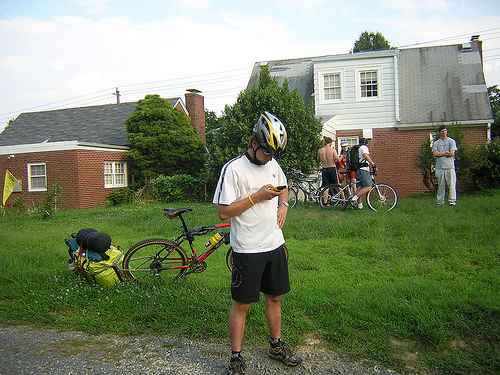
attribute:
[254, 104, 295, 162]
helmet — grey, yellow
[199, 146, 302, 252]
shirt — white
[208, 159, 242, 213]
stripe — black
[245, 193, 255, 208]
wristband — yellow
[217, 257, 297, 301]
shorts — black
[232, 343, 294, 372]
shoes — grey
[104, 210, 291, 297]
bike — red, orange, old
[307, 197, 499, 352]
grass — green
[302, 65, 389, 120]
window — white, upstairs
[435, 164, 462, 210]
pants — white, khaki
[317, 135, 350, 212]
man — shirtless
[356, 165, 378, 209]
shorts — grey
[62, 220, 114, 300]
backpack — packed, green, yellow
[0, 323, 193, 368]
road — gravel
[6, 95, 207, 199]
house — brick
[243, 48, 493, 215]
house — taller, medium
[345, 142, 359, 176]
backpack — black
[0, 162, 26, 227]
flag — yellow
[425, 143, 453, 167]
arms — crossed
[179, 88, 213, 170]
chimney — red